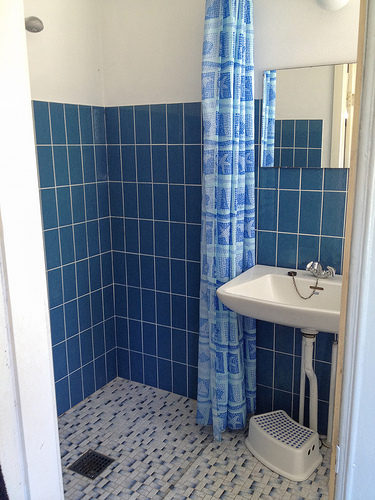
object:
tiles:
[32, 100, 51, 145]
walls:
[24, 0, 360, 438]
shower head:
[24, 16, 44, 34]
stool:
[244, 409, 323, 482]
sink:
[216, 264, 344, 334]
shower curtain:
[196, 0, 257, 443]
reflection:
[261, 69, 277, 167]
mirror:
[260, 62, 357, 168]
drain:
[67, 448, 115, 481]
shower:
[22, 0, 204, 500]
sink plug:
[287, 270, 297, 276]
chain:
[291, 272, 318, 300]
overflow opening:
[310, 286, 325, 291]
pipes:
[299, 335, 318, 432]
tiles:
[225, 472, 236, 483]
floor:
[57, 376, 333, 500]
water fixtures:
[306, 261, 336, 279]